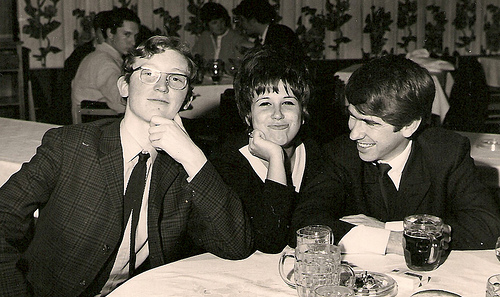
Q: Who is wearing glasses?
A: The man on the left.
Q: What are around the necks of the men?
A: Neckties.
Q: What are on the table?
A: Drinking glasses.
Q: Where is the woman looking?
A: At the camera.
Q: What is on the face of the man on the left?
A: Glasses.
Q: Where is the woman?
A: Between the two men.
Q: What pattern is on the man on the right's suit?
A: Plaid.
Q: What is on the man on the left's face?
A: Glasses.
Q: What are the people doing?
A: Sitting at a table.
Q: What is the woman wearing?
A: A dark colored dress with a white collar.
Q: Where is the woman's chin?
A: Resting in her hand.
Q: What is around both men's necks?
A: Tie.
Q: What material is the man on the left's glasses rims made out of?
A: Metal.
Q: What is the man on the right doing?
A: Smiling.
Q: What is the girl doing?
A: Smiling for the camera.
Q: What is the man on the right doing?
A: Rubbing his chin.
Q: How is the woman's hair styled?
A: Bangs.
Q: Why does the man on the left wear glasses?
A: Vision problem.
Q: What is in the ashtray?
A: Cigarette butts.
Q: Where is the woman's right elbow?
A: On the table.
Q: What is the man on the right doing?
A: Laughing.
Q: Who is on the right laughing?
A: The man.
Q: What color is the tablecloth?
A: White.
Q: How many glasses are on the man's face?
A: One.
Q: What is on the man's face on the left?
A: Glasses.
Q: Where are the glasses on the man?
A: His face.